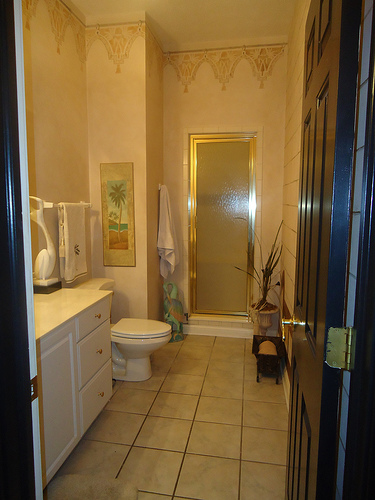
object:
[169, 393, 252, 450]
floor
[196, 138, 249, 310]
shower door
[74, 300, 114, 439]
cabinets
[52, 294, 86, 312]
counter top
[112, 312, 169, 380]
toilet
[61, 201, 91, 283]
towel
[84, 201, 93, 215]
wall hook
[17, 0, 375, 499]
bathroom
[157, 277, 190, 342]
sculpture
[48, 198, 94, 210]
towel holder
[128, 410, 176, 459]
tile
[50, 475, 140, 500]
bathroom rug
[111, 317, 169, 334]
toilet seat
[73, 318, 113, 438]
drawers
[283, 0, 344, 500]
bathroom door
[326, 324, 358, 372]
hinges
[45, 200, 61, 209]
bar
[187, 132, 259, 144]
trim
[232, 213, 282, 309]
plant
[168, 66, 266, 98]
wall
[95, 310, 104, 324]
handles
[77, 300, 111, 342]
drawer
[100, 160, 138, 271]
picture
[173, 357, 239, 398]
tiles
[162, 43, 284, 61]
border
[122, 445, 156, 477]
tile floor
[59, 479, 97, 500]
rug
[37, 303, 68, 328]
counter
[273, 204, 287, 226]
corner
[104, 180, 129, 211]
tree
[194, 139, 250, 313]
mirror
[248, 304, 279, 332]
pot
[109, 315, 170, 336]
cover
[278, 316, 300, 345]
handle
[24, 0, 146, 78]
decorations